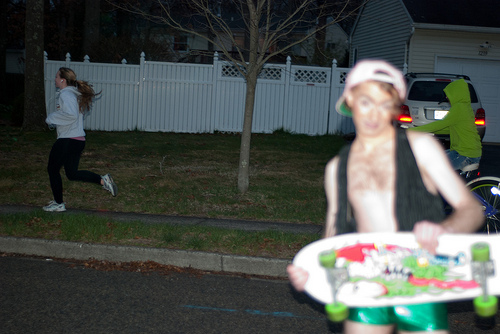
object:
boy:
[280, 45, 492, 334]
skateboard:
[278, 218, 500, 318]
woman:
[29, 57, 127, 218]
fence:
[30, 48, 357, 133]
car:
[402, 68, 490, 144]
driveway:
[76, 195, 315, 239]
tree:
[199, 28, 304, 198]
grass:
[7, 129, 324, 213]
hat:
[333, 59, 417, 117]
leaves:
[72, 253, 215, 276]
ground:
[3, 263, 314, 332]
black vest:
[327, 127, 454, 243]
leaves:
[124, 1, 365, 65]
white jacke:
[39, 85, 90, 141]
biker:
[421, 76, 497, 173]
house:
[337, 1, 500, 143]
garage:
[430, 47, 500, 145]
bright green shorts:
[344, 299, 450, 334]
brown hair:
[55, 64, 105, 115]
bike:
[462, 159, 499, 233]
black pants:
[45, 135, 110, 208]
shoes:
[25, 195, 73, 221]